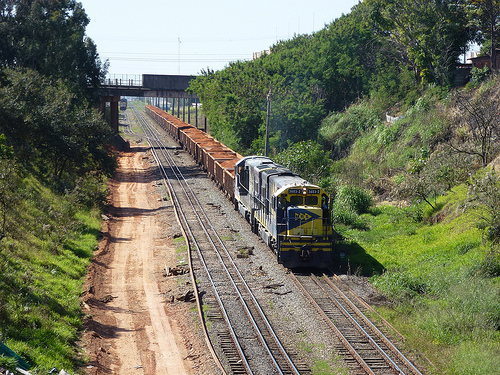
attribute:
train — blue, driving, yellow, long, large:
[233, 152, 338, 270]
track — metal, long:
[126, 102, 301, 373]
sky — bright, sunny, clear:
[1, 1, 362, 105]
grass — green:
[1, 134, 107, 372]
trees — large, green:
[1, 0, 117, 187]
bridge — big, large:
[92, 75, 207, 135]